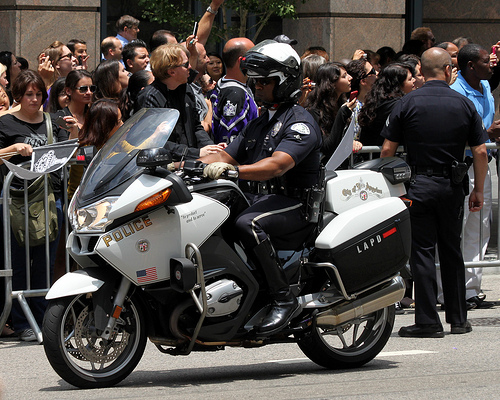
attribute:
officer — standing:
[229, 61, 311, 141]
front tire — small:
[27, 281, 153, 391]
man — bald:
[148, 43, 187, 90]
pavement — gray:
[10, 362, 55, 388]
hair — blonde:
[148, 43, 181, 72]